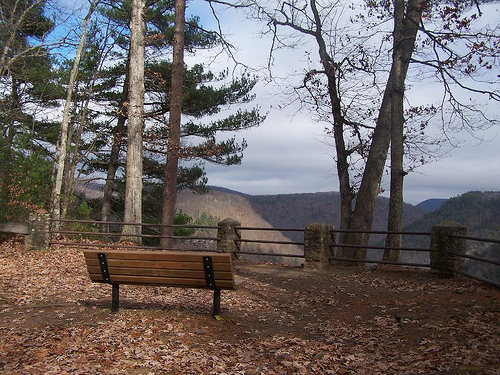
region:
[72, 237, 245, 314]
A wooden bench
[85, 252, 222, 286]
Metal plates on the bench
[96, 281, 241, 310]
Metal stands on the bench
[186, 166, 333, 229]
Hills in the background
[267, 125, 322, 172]
Clouds in the photo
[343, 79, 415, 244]
Tree trunks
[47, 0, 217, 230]
Trees in the photo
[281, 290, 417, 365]
Dry leaves on the ground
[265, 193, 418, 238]
Valleys in the photo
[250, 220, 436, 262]
A fence in the photo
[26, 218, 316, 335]
a bench on the ground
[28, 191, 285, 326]
a wood and metal bench on the ground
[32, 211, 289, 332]
a wood and metal bench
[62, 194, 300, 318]
a bench in a leafy area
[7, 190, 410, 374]
an area with fallen leaves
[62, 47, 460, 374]
a bench overlooking the mountains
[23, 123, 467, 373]
an area with leaves and bench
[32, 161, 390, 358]
a wooden bench overlooking the mountains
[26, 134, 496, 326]
a railing protecting people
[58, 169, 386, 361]
an empty bench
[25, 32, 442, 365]
A wooden bench overlooking the mountains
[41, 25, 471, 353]
The beautiful view in a park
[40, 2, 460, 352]
A view from a vantage point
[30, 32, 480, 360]
The trees are in a park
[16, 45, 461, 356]
The bench is for visitors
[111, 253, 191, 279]
The wood on a park bench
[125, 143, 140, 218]
A tree standing in the forest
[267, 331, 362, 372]
The ground and leaves in a park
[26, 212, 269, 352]
A bench for the convenience of visitors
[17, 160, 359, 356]
A bench made of wood and metal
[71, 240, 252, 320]
bench on the ground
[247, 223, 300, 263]
fencing between two rocks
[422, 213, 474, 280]
gray stone rock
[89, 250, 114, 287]
screws on the bench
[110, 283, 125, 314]
left leg of the bench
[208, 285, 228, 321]
right leg of the bench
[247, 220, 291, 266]
three railings on the fence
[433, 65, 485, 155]
branches on the tree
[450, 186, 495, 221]
mountain of green trees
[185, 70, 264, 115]
fir branches on the tree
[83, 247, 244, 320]
A wooden park bench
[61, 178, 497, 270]
Grass and tree covered mountains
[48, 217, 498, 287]
A fence around the dropoff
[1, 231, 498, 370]
Dead leaf covered ground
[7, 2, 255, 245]
Trees near the park bench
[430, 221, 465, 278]
Cement material fence post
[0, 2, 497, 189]
A cloudy blue sky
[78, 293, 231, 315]
Shadow of a park bench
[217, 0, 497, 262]
Trees that have lost most of their leaves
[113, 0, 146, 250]
The trunk of a tree